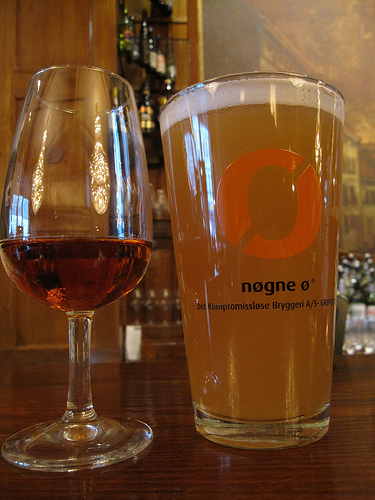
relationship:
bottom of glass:
[2, 417, 154, 471] [1, 405, 154, 480]